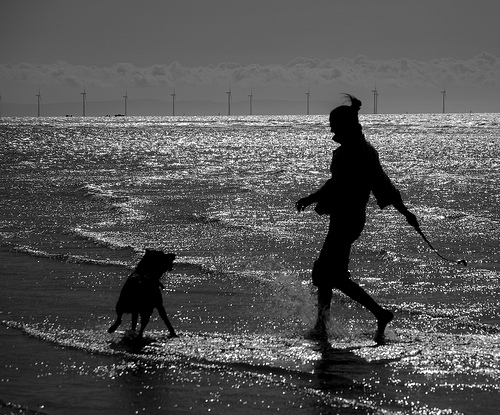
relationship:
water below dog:
[1, 117, 496, 413] [96, 240, 190, 343]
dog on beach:
[96, 240, 190, 343] [0, 120, 450, 414]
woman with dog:
[290, 92, 470, 357] [96, 240, 190, 343]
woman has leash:
[290, 92, 470, 357] [404, 219, 480, 269]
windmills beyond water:
[21, 89, 467, 115] [1, 117, 496, 413]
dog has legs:
[96, 240, 190, 343] [102, 296, 181, 344]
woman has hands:
[290, 92, 470, 357] [289, 194, 425, 231]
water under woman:
[1, 117, 496, 413] [290, 92, 470, 357]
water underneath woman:
[1, 117, 496, 413] [290, 92, 470, 357]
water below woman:
[1, 117, 496, 413] [290, 92, 470, 357]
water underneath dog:
[1, 117, 496, 413] [96, 240, 190, 343]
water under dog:
[1, 117, 496, 413] [96, 240, 190, 343]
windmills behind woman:
[21, 89, 467, 115] [290, 92, 470, 357]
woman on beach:
[290, 92, 470, 357] [0, 120, 450, 414]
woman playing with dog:
[290, 92, 470, 357] [96, 240, 190, 343]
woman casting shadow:
[290, 92, 470, 357] [299, 335, 441, 403]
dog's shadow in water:
[102, 330, 165, 365] [1, 117, 496, 413]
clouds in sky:
[6, 58, 498, 83] [0, 0, 500, 111]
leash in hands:
[404, 219, 480, 269] [289, 194, 425, 231]